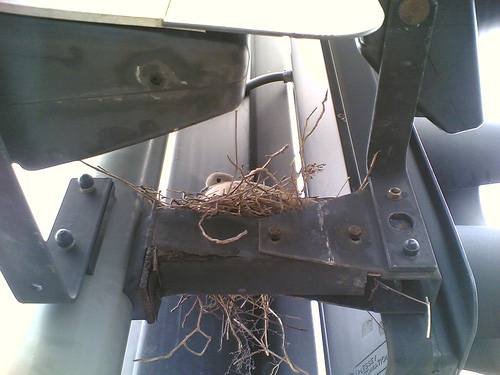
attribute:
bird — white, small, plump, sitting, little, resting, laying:
[172, 151, 270, 188]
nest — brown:
[184, 199, 303, 260]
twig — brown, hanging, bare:
[268, 87, 333, 207]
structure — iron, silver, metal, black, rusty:
[4, 209, 498, 324]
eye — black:
[207, 174, 230, 188]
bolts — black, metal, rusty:
[42, 154, 113, 307]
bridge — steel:
[312, 37, 493, 338]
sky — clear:
[481, 56, 498, 117]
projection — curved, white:
[2, 1, 385, 57]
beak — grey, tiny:
[189, 185, 212, 198]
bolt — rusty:
[390, 224, 438, 262]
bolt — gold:
[370, 185, 414, 200]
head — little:
[199, 165, 235, 192]